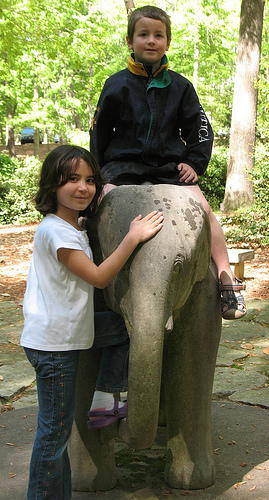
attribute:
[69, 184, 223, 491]
elephant statue — gray